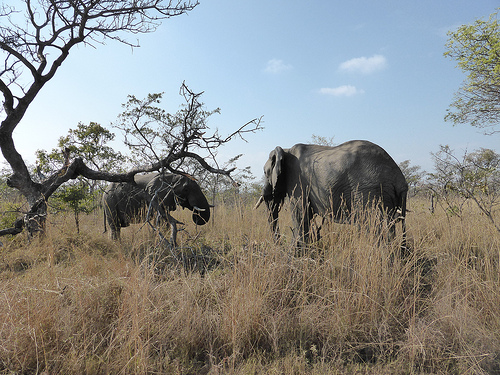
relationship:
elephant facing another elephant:
[254, 140, 412, 259] [101, 172, 217, 242]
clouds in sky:
[0, 0, 500, 188] [1, 0, 500, 194]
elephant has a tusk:
[254, 140, 412, 259] [255, 194, 263, 212]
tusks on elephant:
[193, 201, 217, 211] [101, 172, 217, 242]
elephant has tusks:
[101, 172, 217, 242] [193, 201, 217, 211]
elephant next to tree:
[101, 172, 217, 242] [1, 1, 265, 240]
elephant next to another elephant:
[254, 140, 412, 259] [101, 172, 217, 242]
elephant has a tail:
[101, 172, 217, 242] [101, 203, 108, 235]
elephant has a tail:
[254, 140, 412, 259] [400, 181, 409, 256]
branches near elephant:
[0, 0, 264, 234] [101, 172, 217, 242]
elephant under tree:
[101, 172, 217, 242] [1, 1, 265, 240]